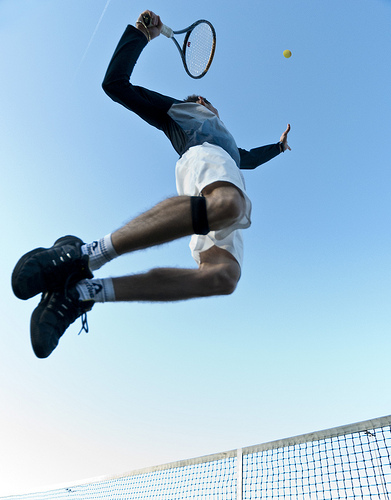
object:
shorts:
[173, 143, 254, 279]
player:
[9, 8, 291, 363]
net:
[0, 416, 390, 498]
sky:
[1, 2, 390, 497]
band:
[189, 194, 210, 237]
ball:
[282, 48, 293, 59]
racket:
[140, 12, 219, 81]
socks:
[77, 233, 120, 273]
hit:
[185, 22, 292, 76]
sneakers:
[13, 233, 92, 302]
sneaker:
[29, 290, 91, 361]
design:
[85, 280, 104, 300]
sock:
[77, 277, 117, 306]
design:
[86, 240, 100, 257]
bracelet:
[133, 19, 152, 44]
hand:
[135, 11, 165, 40]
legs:
[83, 229, 247, 304]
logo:
[85, 239, 100, 256]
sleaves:
[238, 144, 280, 169]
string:
[190, 33, 214, 47]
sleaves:
[98, 23, 172, 135]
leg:
[91, 145, 249, 266]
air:
[289, 32, 298, 52]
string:
[287, 442, 294, 499]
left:
[30, 275, 95, 358]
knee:
[209, 192, 242, 232]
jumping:
[8, 190, 290, 366]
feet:
[30, 273, 97, 363]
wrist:
[129, 14, 159, 43]